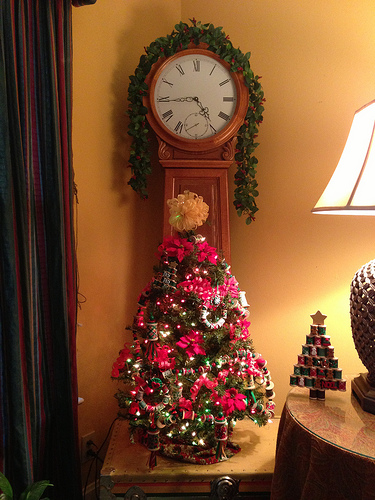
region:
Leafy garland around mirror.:
[115, 79, 165, 213]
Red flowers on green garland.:
[165, 20, 256, 50]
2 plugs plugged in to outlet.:
[78, 425, 121, 486]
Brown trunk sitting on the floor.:
[104, 454, 172, 489]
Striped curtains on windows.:
[23, 320, 95, 429]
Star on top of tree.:
[304, 302, 326, 333]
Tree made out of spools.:
[294, 320, 338, 399]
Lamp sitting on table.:
[350, 272, 372, 360]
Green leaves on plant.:
[22, 469, 41, 496]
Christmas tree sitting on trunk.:
[142, 399, 246, 480]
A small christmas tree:
[102, 199, 269, 462]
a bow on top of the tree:
[161, 185, 211, 230]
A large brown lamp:
[307, 98, 374, 413]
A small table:
[290, 359, 374, 498]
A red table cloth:
[276, 366, 374, 498]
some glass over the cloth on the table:
[289, 365, 374, 460]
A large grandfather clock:
[112, 21, 267, 393]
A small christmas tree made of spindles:
[286, 304, 343, 404]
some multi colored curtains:
[1, 5, 97, 483]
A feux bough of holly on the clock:
[120, 9, 267, 225]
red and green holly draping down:
[124, 88, 152, 193]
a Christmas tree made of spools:
[285, 304, 346, 404]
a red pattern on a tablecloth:
[291, 441, 331, 498]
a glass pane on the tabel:
[324, 416, 355, 435]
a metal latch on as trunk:
[211, 477, 253, 498]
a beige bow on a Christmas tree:
[160, 193, 213, 227]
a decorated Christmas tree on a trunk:
[105, 192, 260, 464]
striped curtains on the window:
[17, 212, 67, 440]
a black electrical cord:
[108, 420, 111, 441]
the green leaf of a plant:
[25, 480, 55, 497]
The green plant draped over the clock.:
[123, 26, 271, 236]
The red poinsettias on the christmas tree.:
[145, 239, 278, 432]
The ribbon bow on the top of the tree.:
[163, 184, 211, 245]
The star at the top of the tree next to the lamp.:
[311, 297, 323, 332]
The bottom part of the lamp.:
[339, 244, 374, 404]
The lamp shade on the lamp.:
[324, 92, 374, 214]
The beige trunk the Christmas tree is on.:
[96, 409, 289, 499]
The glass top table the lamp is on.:
[285, 375, 374, 458]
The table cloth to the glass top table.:
[281, 403, 359, 498]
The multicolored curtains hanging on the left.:
[5, 19, 104, 497]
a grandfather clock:
[116, 7, 279, 316]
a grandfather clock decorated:
[94, 4, 319, 366]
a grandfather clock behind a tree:
[97, 8, 302, 464]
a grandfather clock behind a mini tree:
[83, 12, 305, 480]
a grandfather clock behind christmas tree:
[114, 27, 324, 459]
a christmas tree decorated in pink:
[83, 158, 283, 469]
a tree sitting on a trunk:
[109, 182, 289, 488]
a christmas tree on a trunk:
[68, 161, 292, 499]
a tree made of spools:
[273, 296, 366, 419]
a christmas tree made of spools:
[260, 290, 354, 442]